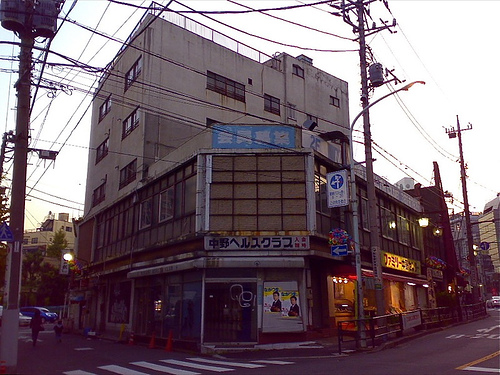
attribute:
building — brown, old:
[103, 40, 365, 256]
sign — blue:
[205, 125, 305, 151]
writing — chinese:
[223, 133, 289, 144]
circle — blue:
[327, 175, 347, 191]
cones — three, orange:
[122, 330, 187, 353]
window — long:
[171, 183, 188, 239]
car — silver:
[483, 292, 499, 308]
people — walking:
[26, 306, 67, 351]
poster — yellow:
[264, 287, 305, 319]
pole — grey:
[349, 211, 372, 349]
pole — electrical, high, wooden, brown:
[348, 22, 395, 321]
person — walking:
[32, 308, 45, 346]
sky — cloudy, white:
[354, 27, 499, 118]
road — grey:
[33, 342, 128, 368]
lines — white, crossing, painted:
[135, 351, 227, 374]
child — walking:
[53, 318, 67, 342]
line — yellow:
[460, 353, 500, 364]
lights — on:
[418, 211, 443, 233]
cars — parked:
[17, 303, 56, 326]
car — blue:
[25, 305, 55, 321]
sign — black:
[280, 290, 305, 318]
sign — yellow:
[384, 252, 432, 274]